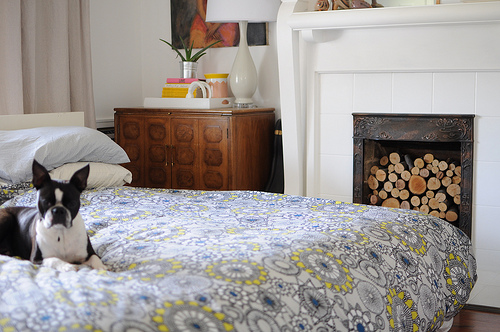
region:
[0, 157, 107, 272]
black and white dog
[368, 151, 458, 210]
stacked wood in fireplace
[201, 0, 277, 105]
tall white lamp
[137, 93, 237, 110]
the white serving tray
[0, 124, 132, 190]
two stacked pillows on bed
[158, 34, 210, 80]
silver tin with greens in it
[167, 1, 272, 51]
bottom picture hanging on wall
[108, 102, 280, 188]
top half of wooden furniture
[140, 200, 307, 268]
portion of top of bedspread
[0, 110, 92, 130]
top of bed headboard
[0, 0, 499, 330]
Black and white dog in the bedroom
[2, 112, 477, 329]
Dog lying down on the bed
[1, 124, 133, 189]
Two pillows on the right side of bed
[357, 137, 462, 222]
Wooden logs in the fireplace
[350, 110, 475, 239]
Fireplace in the bedroom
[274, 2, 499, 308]
Fire place with white mantle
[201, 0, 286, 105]
White lamp and shade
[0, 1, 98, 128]
Curtain behind the bed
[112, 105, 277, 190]
Wooden lamp stand beside the fireplace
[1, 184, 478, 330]
Yellow, blue and white floral comforter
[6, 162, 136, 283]
white and black dog laying down on the bed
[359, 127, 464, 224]
logs as decoration piece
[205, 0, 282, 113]
white lamp on a wooden cabinet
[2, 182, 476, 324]
yellow, blue and white bed comforter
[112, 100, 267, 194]
wooden cabinet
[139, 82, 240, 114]
white wooden container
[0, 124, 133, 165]
light blue pillow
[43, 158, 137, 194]
white pillow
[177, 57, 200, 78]
steel plant holder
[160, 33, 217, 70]
green plant in a steel pot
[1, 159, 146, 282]
A BLACK AND WHITE DOG ON A BED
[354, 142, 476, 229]
A PILE OF WOOD IN A FIRE PLACE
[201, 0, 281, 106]
A WHITE LAMP ON A DRESSER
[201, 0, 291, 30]
A WHITE LAMP SHADE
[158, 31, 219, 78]
A PLANT ON A DRESSER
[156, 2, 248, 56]
A PICTURE HANGING ON THE WALL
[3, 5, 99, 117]
A WHITE CURTAIN PANEL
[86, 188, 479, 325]
A FLOWERED BED SPREAD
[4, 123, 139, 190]
TWO PILLOW ON THE BED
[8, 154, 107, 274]
A DOG LOOKING STRAIGHT AHEAD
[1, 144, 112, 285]
Black and white dog lying on bed.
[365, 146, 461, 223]
End of logs in fireplace.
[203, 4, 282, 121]
White lamp on dresser.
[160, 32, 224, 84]
Sliver can holding green plant.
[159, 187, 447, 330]
Gray, yellow and blue print bedspread.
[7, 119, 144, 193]
Two pillows at head of bed.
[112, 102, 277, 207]
Brown dresser next to fireplace.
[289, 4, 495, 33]
White mantel above fireplace.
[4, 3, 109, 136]
White drapes over window.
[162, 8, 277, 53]
Bottom of picture hanging on wall.